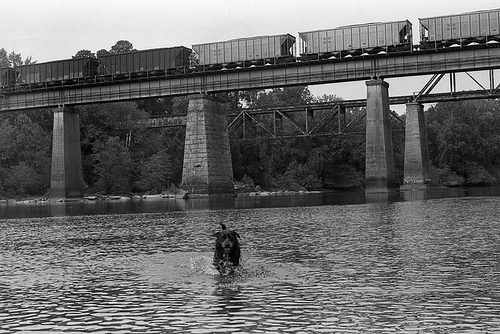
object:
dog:
[208, 219, 250, 280]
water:
[3, 185, 498, 331]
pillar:
[179, 91, 241, 199]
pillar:
[363, 77, 398, 196]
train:
[5, 7, 500, 89]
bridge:
[1, 39, 499, 115]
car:
[190, 31, 297, 73]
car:
[91, 42, 195, 82]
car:
[417, 6, 499, 51]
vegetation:
[1, 36, 499, 190]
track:
[3, 9, 499, 91]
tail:
[215, 219, 228, 229]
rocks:
[87, 191, 180, 202]